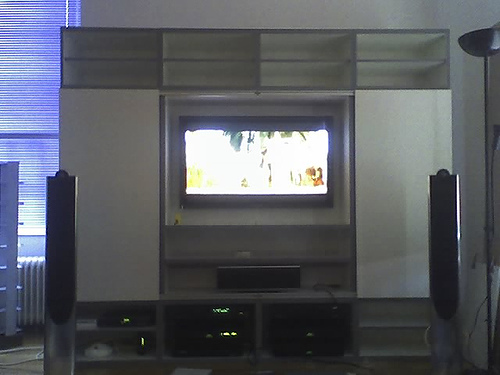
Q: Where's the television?
A: Living room.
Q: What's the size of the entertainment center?
A: Large.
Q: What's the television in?
A: Entertainment center.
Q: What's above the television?
A: Shelves.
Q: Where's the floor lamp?
A: Next to entertainment center.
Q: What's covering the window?
A: Blinds.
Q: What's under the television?
A: Speaker.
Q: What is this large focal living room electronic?
A: Tv.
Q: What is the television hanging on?
A: Wall.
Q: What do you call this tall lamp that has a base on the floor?
A: Floor lamp.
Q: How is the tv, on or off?
A: On.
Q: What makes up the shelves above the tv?
A: Wood.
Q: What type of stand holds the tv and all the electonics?
A: Entertainment Stand.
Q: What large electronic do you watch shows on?
A: Television.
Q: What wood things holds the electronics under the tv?
A: Shelves.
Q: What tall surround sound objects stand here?
A: Speaker.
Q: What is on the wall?
A: A tv screen.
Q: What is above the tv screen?
A: Shelves.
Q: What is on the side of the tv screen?
A: A speaker.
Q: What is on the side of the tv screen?
A: A speaker.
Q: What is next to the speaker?
A: A lamp.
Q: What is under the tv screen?
A: A shelf.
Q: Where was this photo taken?
A: Living room.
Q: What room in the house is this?
A: Living room.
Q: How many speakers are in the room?
A: Three.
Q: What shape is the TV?
A: Rectangle.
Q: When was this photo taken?
A: Daytime.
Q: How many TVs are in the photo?
A: One.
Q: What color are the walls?
A: White.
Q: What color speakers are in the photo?
A: Black.